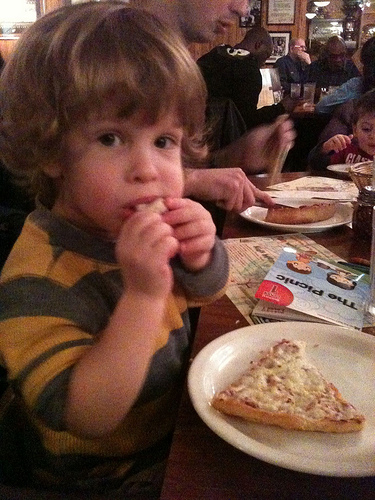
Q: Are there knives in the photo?
A: Yes, there is a knife.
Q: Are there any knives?
A: Yes, there is a knife.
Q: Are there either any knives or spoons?
A: Yes, there is a knife.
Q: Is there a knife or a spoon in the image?
A: Yes, there is a knife.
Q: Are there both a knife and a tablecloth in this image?
A: No, there is a knife but no tablecloths.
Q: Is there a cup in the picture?
A: No, there are no cups.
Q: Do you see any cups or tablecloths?
A: No, there are no cups or tablecloths.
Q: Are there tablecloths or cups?
A: No, there are no cups or tablecloths.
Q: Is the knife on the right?
A: Yes, the knife is on the right of the image.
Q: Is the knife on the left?
A: No, the knife is on the right of the image.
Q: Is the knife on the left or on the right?
A: The knife is on the right of the image.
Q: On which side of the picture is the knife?
A: The knife is on the right of the image.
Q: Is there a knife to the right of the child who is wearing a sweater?
A: Yes, there is a knife to the right of the kid.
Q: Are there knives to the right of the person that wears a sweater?
A: Yes, there is a knife to the right of the kid.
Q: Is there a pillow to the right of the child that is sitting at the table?
A: No, there is a knife to the right of the child.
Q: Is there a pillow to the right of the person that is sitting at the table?
A: No, there is a knife to the right of the child.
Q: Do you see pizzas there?
A: Yes, there is a pizza.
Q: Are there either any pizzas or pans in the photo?
A: Yes, there is a pizza.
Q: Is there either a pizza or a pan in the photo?
A: Yes, there is a pizza.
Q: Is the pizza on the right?
A: Yes, the pizza is on the right of the image.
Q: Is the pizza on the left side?
A: No, the pizza is on the right of the image.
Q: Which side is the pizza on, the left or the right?
A: The pizza is on the right of the image.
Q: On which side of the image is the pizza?
A: The pizza is on the right of the image.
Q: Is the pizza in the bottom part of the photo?
A: Yes, the pizza is in the bottom of the image.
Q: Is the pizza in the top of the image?
A: No, the pizza is in the bottom of the image.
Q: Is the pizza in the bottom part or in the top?
A: The pizza is in the bottom of the image.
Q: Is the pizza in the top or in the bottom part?
A: The pizza is in the bottom of the image.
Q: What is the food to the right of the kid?
A: The food is a pizza.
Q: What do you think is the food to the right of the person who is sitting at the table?
A: The food is a pizza.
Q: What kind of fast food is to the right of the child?
A: The food is a pizza.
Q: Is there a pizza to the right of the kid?
A: Yes, there is a pizza to the right of the kid.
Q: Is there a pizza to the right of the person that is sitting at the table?
A: Yes, there is a pizza to the right of the kid.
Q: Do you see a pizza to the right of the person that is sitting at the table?
A: Yes, there is a pizza to the right of the kid.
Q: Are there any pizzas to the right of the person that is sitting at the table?
A: Yes, there is a pizza to the right of the kid.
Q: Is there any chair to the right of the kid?
A: No, there is a pizza to the right of the kid.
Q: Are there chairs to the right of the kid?
A: No, there is a pizza to the right of the kid.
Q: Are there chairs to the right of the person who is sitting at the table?
A: No, there is a pizza to the right of the kid.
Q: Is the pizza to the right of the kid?
A: Yes, the pizza is to the right of the kid.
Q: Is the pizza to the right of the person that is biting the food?
A: Yes, the pizza is to the right of the kid.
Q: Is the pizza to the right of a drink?
A: No, the pizza is to the right of the kid.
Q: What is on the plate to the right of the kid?
A: The pizza is on the plate.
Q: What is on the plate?
A: The pizza is on the plate.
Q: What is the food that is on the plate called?
A: The food is a pizza.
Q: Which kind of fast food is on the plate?
A: The food is a pizza.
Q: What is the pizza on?
A: The pizza is on the plate.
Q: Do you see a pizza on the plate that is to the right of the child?
A: Yes, there is a pizza on the plate.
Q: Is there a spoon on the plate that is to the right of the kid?
A: No, there is a pizza on the plate.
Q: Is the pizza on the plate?
A: Yes, the pizza is on the plate.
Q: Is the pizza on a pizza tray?
A: No, the pizza is on the plate.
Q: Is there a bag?
A: No, there are no bags.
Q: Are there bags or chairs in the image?
A: No, there are no bags or chairs.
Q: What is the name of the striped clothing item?
A: The clothing item is a sweater.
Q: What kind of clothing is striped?
A: The clothing is a sweater.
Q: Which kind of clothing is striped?
A: The clothing is a sweater.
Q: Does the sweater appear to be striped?
A: Yes, the sweater is striped.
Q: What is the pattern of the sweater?
A: The sweater is striped.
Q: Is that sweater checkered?
A: No, the sweater is striped.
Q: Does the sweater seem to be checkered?
A: No, the sweater is striped.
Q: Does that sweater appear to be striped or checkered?
A: The sweater is striped.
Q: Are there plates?
A: Yes, there is a plate.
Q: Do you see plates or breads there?
A: Yes, there is a plate.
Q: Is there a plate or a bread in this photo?
A: Yes, there is a plate.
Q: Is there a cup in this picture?
A: No, there are no cups.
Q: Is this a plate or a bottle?
A: This is a plate.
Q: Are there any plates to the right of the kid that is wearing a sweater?
A: Yes, there is a plate to the right of the child.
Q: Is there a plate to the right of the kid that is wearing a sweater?
A: Yes, there is a plate to the right of the child.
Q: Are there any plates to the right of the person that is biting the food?
A: Yes, there is a plate to the right of the child.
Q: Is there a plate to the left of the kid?
A: No, the plate is to the right of the kid.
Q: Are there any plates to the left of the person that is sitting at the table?
A: No, the plate is to the right of the kid.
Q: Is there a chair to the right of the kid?
A: No, there is a plate to the right of the kid.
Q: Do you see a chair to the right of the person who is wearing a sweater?
A: No, there is a plate to the right of the kid.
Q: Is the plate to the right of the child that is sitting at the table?
A: Yes, the plate is to the right of the child.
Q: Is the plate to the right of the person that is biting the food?
A: Yes, the plate is to the right of the child.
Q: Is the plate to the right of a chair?
A: No, the plate is to the right of the child.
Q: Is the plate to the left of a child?
A: No, the plate is to the right of a child.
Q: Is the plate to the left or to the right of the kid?
A: The plate is to the right of the kid.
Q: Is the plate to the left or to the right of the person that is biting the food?
A: The plate is to the right of the kid.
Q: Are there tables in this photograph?
A: Yes, there is a table.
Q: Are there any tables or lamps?
A: Yes, there is a table.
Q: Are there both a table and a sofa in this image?
A: No, there is a table but no sofas.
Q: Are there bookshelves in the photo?
A: No, there are no bookshelves.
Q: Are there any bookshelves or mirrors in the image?
A: No, there are no bookshelves or mirrors.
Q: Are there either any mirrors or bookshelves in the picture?
A: No, there are no bookshelves or mirrors.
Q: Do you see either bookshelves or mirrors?
A: No, there are no bookshelves or mirrors.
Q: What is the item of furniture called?
A: The piece of furniture is a table.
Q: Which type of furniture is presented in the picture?
A: The furniture is a table.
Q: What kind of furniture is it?
A: The piece of furniture is a table.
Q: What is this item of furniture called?
A: This is a table.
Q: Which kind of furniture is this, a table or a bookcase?
A: This is a table.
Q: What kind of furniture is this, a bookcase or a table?
A: This is a table.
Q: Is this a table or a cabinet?
A: This is a table.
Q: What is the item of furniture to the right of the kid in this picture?
A: The piece of furniture is a table.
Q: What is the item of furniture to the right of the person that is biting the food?
A: The piece of furniture is a table.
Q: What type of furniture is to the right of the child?
A: The piece of furniture is a table.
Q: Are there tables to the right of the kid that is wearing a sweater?
A: Yes, there is a table to the right of the child.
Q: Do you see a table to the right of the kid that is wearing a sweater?
A: Yes, there is a table to the right of the child.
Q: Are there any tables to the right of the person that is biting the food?
A: Yes, there is a table to the right of the child.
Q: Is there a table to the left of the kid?
A: No, the table is to the right of the kid.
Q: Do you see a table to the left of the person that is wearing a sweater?
A: No, the table is to the right of the kid.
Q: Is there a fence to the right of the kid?
A: No, there is a table to the right of the kid.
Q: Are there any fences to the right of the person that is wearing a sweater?
A: No, there is a table to the right of the kid.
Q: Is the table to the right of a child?
A: Yes, the table is to the right of a child.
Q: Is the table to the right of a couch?
A: No, the table is to the right of a child.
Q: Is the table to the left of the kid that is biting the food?
A: No, the table is to the right of the child.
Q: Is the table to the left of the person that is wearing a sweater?
A: No, the table is to the right of the child.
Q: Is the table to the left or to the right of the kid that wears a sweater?
A: The table is to the right of the child.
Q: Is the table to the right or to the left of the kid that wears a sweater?
A: The table is to the right of the child.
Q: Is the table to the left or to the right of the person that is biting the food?
A: The table is to the right of the child.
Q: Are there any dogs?
A: No, there are no dogs.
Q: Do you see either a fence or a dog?
A: No, there are no dogs or fences.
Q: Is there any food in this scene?
A: Yes, there is food.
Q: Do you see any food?
A: Yes, there is food.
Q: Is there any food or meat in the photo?
A: Yes, there is food.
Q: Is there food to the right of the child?
A: Yes, there is food to the right of the child.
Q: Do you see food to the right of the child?
A: Yes, there is food to the right of the child.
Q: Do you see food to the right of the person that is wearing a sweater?
A: Yes, there is food to the right of the child.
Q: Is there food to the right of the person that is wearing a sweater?
A: Yes, there is food to the right of the child.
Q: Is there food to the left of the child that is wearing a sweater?
A: No, the food is to the right of the kid.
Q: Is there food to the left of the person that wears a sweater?
A: No, the food is to the right of the kid.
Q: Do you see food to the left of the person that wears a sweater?
A: No, the food is to the right of the kid.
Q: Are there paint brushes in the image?
A: No, there are no paint brushes.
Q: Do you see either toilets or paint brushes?
A: No, there are no paint brushes or toilets.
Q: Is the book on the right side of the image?
A: Yes, the book is on the right of the image.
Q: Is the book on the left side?
A: No, the book is on the right of the image.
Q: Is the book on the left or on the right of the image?
A: The book is on the right of the image.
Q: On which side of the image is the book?
A: The book is on the right of the image.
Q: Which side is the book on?
A: The book is on the right of the image.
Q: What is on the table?
A: The book is on the table.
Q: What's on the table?
A: The book is on the table.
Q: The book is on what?
A: The book is on the table.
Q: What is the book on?
A: The book is on the table.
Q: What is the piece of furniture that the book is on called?
A: The piece of furniture is a table.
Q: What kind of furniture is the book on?
A: The book is on the table.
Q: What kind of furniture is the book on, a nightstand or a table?
A: The book is on a table.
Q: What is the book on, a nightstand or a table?
A: The book is on a table.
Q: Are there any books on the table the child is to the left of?
A: Yes, there is a book on the table.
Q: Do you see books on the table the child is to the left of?
A: Yes, there is a book on the table.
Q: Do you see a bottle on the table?
A: No, there is a book on the table.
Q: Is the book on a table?
A: Yes, the book is on a table.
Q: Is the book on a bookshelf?
A: No, the book is on a table.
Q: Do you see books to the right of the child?
A: Yes, there is a book to the right of the child.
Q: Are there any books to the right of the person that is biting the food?
A: Yes, there is a book to the right of the child.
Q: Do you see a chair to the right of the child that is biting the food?
A: No, there is a book to the right of the child.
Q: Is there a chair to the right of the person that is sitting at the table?
A: No, there is a book to the right of the child.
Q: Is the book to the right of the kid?
A: Yes, the book is to the right of the kid.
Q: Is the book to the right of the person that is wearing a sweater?
A: Yes, the book is to the right of the kid.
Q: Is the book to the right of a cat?
A: No, the book is to the right of the kid.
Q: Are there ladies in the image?
A: No, there are no ladies.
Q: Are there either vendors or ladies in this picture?
A: No, there are no ladies or vendors.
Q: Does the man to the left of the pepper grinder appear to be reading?
A: Yes, the man is reading.